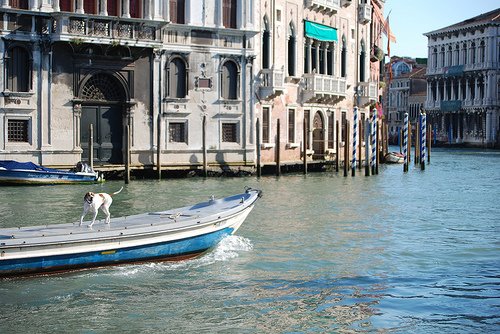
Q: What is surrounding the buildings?
A: Water.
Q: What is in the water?
A: A boat.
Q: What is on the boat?
A: A dog.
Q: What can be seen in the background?
A: Buildings.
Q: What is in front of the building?
A: Brown poles.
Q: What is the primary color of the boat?
A: Blue.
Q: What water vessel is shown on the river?
A: A blue and white boat.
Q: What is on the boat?
A: A dog.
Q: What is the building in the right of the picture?
A: A three story white building.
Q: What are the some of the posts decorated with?
A: Spiral stripes.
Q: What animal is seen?
A: Dog.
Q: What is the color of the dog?
A: Mainly white.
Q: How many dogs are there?
A: One.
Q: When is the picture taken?
A: Daytime.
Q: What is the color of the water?
A: Blue.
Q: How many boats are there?
A: 1.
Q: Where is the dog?
A: In the boat.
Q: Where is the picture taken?
A: On a canal.